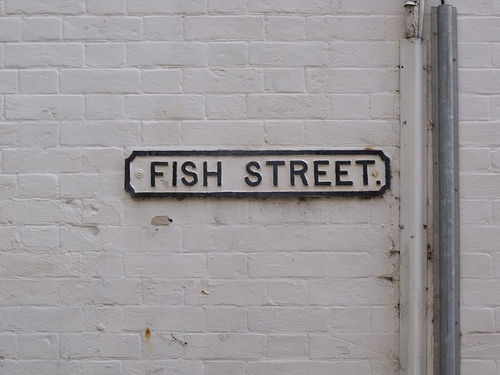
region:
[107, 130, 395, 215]
black and white sign attached to building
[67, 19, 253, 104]
brick wall painted white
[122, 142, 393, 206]
black letters on a white sign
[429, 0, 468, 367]
metal pole against the wall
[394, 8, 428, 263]
white pole going down the white wall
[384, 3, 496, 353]
two pipes containing wires against the wall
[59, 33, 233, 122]
wall made of bricks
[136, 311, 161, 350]
rust spot on wall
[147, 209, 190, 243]
peeled paint on the wall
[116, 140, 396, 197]
white sign with black border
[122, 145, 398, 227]
sign on the brick wall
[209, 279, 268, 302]
white brick forming wall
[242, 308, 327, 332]
white brick forming wall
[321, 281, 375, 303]
white brick forming wall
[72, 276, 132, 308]
white brick forming wall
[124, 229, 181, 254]
white brick forming wall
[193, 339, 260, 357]
white brick forming wall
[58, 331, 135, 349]
white brick forming wall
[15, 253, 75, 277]
white brick forming wall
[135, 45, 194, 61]
white brick forming wall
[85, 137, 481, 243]
sign says Fish Street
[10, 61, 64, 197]
a white bricked wall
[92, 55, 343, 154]
a white bricked wall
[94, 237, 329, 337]
a white bricked wall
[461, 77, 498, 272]
a white bricked wall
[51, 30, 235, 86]
a white bricked wall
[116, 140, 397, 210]
street sign on wall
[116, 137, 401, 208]
sign bolted to wall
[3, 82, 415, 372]
brick wall painted white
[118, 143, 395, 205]
sign painted black and white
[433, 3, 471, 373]
metal pipe on wall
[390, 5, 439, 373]
wire protector painted white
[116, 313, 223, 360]
discoloration on painted wall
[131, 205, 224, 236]
chip on painted wall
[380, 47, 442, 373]
wire protector bolted to wall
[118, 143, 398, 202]
street identification sign on wall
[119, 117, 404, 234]
black and white sign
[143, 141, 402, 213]
black letters on sign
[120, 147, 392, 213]
long and rectangular sign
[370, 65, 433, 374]
white pipe next to sign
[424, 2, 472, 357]
grey pipe near white pipe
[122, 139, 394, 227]
sign on white wall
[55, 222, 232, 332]
white wall is brick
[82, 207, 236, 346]
paint is peeling on wall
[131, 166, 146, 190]
white screw on white sign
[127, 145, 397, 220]
black border on sign